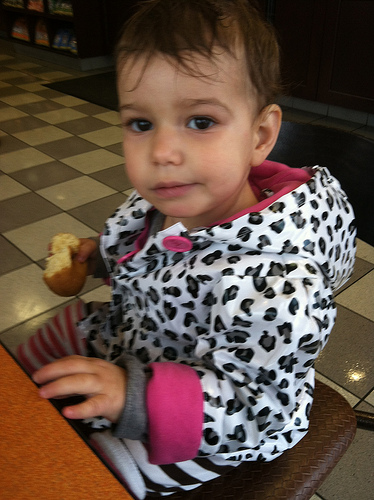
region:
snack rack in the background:
[2, 2, 114, 69]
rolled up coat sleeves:
[110, 349, 206, 462]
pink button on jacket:
[162, 232, 190, 251]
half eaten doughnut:
[42, 232, 86, 295]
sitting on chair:
[149, 375, 364, 497]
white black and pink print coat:
[87, 152, 357, 461]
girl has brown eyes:
[120, 109, 225, 133]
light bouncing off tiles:
[324, 330, 372, 393]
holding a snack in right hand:
[41, 229, 105, 290]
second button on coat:
[116, 229, 141, 269]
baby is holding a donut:
[27, 61, 246, 334]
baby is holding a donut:
[16, 111, 143, 346]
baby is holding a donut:
[37, 214, 147, 330]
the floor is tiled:
[5, 175, 79, 235]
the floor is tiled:
[319, 276, 372, 380]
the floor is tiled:
[20, 193, 102, 238]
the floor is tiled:
[4, 250, 61, 329]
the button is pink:
[151, 228, 199, 276]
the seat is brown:
[242, 369, 332, 484]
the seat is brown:
[213, 447, 305, 498]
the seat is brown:
[266, 419, 339, 494]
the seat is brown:
[294, 394, 371, 455]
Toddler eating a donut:
[23, 2, 356, 498]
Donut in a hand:
[35, 225, 101, 303]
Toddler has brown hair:
[109, 3, 286, 220]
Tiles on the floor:
[0, 50, 372, 497]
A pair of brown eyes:
[123, 107, 221, 137]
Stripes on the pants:
[16, 298, 235, 498]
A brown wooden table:
[1, 339, 134, 498]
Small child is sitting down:
[14, 2, 362, 497]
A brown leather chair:
[190, 377, 360, 497]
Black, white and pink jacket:
[76, 156, 359, 464]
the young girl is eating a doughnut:
[41, 24, 271, 479]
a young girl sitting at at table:
[64, 3, 346, 460]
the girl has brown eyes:
[113, 95, 243, 138]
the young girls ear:
[238, 84, 284, 174]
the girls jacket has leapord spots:
[161, 258, 318, 424]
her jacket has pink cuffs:
[143, 350, 207, 469]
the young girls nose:
[145, 134, 189, 172]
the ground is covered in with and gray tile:
[7, 107, 121, 206]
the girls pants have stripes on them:
[20, 309, 104, 359]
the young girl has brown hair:
[103, 10, 298, 108]